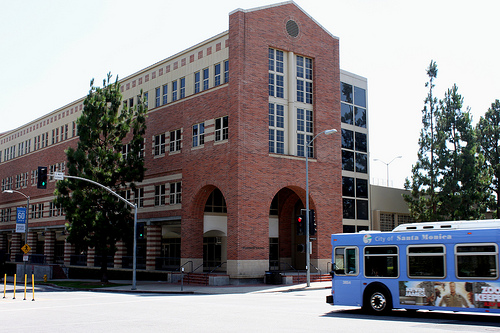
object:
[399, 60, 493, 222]
tree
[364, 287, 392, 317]
chrome wheel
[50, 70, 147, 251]
leaves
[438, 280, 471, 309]
zookeeper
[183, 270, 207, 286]
stairs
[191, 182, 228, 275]
arched entryway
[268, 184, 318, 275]
arched entryway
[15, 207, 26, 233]
sign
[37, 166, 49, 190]
green stoplight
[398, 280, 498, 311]
ad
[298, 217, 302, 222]
light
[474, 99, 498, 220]
tree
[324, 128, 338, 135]
light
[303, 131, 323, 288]
pole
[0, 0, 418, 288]
building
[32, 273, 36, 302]
pole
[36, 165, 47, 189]
traffic signal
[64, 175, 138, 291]
pole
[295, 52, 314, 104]
window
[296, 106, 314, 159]
window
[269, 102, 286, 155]
window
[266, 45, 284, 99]
window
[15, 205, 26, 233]
flag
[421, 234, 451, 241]
letter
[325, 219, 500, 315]
blue bus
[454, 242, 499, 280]
dark window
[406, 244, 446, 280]
dark window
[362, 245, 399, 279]
dark window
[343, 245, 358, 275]
dark window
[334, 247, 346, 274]
dark window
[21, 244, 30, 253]
sign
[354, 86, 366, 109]
window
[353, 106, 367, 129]
window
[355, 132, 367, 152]
window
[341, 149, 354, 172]
window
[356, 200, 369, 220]
window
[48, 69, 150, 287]
tree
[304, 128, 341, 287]
street light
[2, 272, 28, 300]
poles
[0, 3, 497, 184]
sky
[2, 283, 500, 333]
street